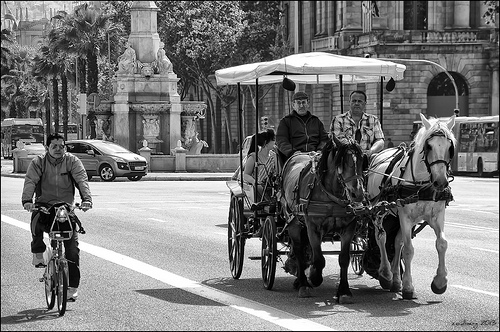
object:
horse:
[278, 135, 366, 304]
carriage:
[214, 50, 404, 293]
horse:
[360, 114, 458, 302]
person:
[21, 131, 94, 299]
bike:
[26, 201, 95, 319]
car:
[58, 137, 148, 181]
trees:
[83, 1, 101, 140]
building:
[180, 1, 499, 173]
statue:
[91, 0, 206, 153]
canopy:
[214, 49, 406, 86]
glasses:
[49, 143, 66, 149]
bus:
[423, 115, 500, 176]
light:
[75, 92, 92, 139]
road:
[1, 174, 498, 330]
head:
[45, 134, 66, 159]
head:
[320, 133, 366, 212]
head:
[416, 113, 459, 193]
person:
[275, 92, 328, 162]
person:
[330, 91, 384, 157]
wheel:
[225, 193, 246, 279]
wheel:
[260, 215, 280, 290]